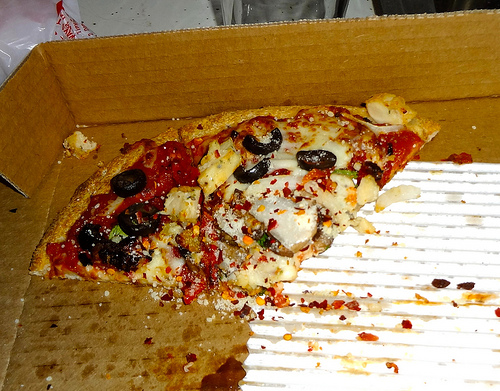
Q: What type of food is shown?
A: Pizza.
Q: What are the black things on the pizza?
A: Olives.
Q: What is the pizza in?
A: Box.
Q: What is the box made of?
A: Cardboard.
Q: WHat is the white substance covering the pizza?
A: Cheese.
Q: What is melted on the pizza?
A: Cheese.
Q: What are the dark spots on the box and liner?
A: Grease.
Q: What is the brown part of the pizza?
A: Crust.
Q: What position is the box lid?
A: Open.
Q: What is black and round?
A: Olive.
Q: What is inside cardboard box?
A: Pizza.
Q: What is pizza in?
A: Cardboard box.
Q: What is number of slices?
A: Two.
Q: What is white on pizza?
A: Cheese.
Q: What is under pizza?
A: White paper.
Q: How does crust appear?
A: Thin.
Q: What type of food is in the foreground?
A: Pizza.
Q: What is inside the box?
A: Pizza.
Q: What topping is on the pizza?
A: Black olives.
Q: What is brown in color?
A: The box.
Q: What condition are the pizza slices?
A: Fully cooked.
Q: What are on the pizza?
A: Toppings.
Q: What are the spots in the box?
A: Grease.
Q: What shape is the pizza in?
A: Triangle.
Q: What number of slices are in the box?
A: Two.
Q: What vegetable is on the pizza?
A: Olives.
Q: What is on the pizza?
A: Black olives.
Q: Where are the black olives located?
A: On the pizza.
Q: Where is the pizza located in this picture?
A: In a box.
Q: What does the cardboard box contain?
A: The pizza.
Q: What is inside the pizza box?
A: Pizza.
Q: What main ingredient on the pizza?
A: Tomato sauce.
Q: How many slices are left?
A: 2.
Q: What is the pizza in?
A: Box.